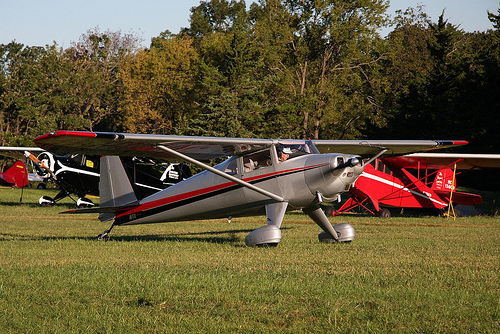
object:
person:
[277, 144, 293, 162]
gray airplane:
[33, 114, 467, 249]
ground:
[0, 244, 498, 334]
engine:
[331, 154, 366, 177]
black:
[128, 164, 156, 186]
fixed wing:
[33, 131, 466, 159]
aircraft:
[32, 130, 467, 247]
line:
[118, 160, 329, 223]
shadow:
[1, 227, 295, 247]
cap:
[283, 146, 293, 154]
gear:
[97, 220, 117, 245]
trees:
[0, 0, 497, 131]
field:
[0, 172, 500, 334]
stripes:
[30, 130, 125, 139]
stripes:
[435, 140, 471, 146]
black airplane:
[34, 148, 194, 208]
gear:
[243, 223, 282, 247]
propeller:
[328, 154, 371, 172]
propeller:
[21, 150, 58, 179]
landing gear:
[245, 202, 290, 247]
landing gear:
[301, 205, 355, 241]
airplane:
[334, 152, 485, 216]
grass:
[0, 185, 498, 332]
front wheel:
[318, 222, 356, 245]